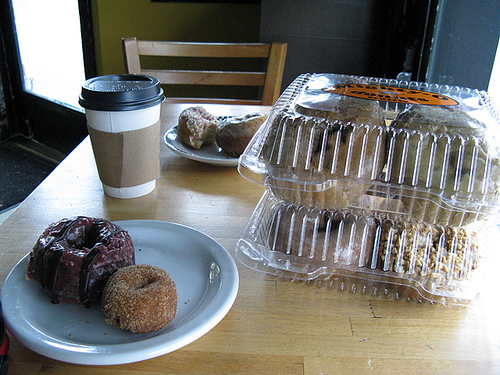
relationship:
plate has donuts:
[0, 219, 239, 367] [27, 216, 178, 336]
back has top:
[125, 36, 287, 107] [118, 31, 295, 66]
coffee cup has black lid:
[75, 70, 165, 200] [78, 71, 164, 111]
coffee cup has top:
[77, 72, 168, 198] [72, 68, 168, 111]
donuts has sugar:
[27, 216, 178, 336] [133, 293, 149, 304]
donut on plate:
[178, 103, 216, 150] [163, 112, 273, 167]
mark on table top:
[336, 309, 366, 339] [0, 102, 488, 374]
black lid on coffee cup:
[78, 73, 167, 112] [79, 69, 166, 189]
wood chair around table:
[122, 32, 289, 98] [11, 102, 478, 342]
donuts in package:
[264, 206, 483, 300] [228, 56, 498, 317]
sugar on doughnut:
[42, 217, 121, 267] [106, 264, 178, 333]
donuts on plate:
[27, 216, 178, 336] [0, 210, 239, 373]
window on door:
[12, 3, 94, 109] [3, 0, 111, 175]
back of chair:
[125, 36, 285, 110] [118, 29, 289, 109]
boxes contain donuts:
[236, 69, 498, 311] [263, 88, 497, 288]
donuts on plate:
[27, 216, 178, 336] [125, 213, 235, 304]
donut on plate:
[178, 106, 218, 150] [166, 105, 278, 164]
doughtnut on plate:
[213, 103, 266, 154] [166, 105, 278, 164]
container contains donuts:
[243, 70, 499, 227] [263, 88, 499, 305]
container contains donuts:
[244, 184, 499, 299] [263, 88, 499, 305]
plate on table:
[0, 210, 239, 373] [0, 102, 498, 374]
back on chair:
[125, 36, 287, 107] [119, 33, 291, 101]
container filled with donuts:
[244, 184, 499, 299] [269, 206, 484, 300]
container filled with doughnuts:
[238, 72, 498, 227] [274, 71, 499, 221]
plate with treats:
[0, 210, 239, 373] [26, 214, 177, 333]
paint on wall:
[92, 0, 268, 115] [1, 1, 498, 177]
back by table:
[125, 36, 287, 107] [0, 102, 498, 374]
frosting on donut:
[30, 216, 128, 301] [75, 257, 186, 342]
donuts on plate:
[27, 210, 187, 341] [0, 210, 239, 373]